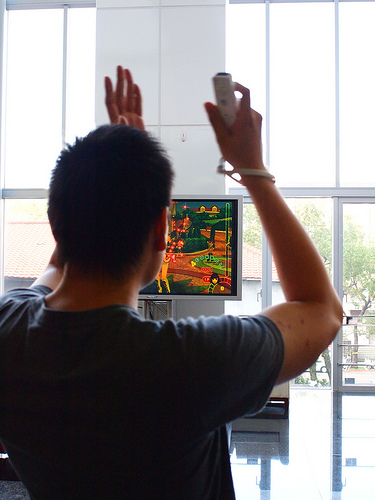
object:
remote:
[211, 71, 238, 130]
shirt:
[0, 284, 284, 499]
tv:
[117, 194, 244, 302]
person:
[0, 64, 345, 500]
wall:
[96, 0, 227, 344]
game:
[138, 201, 233, 293]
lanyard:
[215, 157, 274, 182]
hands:
[202, 83, 264, 169]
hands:
[103, 63, 147, 136]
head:
[45, 120, 174, 290]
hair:
[47, 123, 174, 277]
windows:
[0, 1, 375, 392]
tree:
[241, 196, 375, 383]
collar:
[38, 295, 140, 325]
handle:
[343, 314, 351, 323]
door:
[337, 197, 375, 393]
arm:
[204, 166, 345, 423]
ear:
[154, 205, 168, 251]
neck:
[48, 262, 143, 315]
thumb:
[202, 101, 228, 139]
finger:
[233, 79, 252, 114]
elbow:
[333, 297, 345, 329]